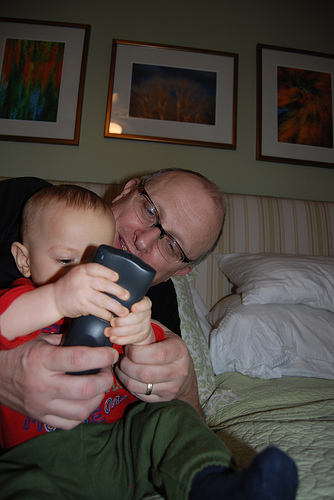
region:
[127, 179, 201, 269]
man wearing reading glasses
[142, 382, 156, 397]
man wearing a wedding ring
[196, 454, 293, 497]
baby wearing blue socks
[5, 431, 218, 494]
man wearing green pants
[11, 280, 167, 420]
baby wearing a red shirt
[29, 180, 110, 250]
baby with blonde hair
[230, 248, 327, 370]
pillows on the bed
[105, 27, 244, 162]
pictures on the wall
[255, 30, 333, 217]
pictures on the wall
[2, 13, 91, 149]
pictures on the wall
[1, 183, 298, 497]
a baby looking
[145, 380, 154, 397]
a ring on finger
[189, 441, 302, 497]
a navy blue sock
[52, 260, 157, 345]
the baby's hand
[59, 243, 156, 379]
a black remote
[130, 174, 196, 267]
glasses on face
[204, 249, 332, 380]
pillows stacked to right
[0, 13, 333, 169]
frames on the wall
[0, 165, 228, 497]
a man holding baby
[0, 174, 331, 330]
a bed frame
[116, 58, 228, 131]
A painting in the center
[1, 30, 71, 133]
A painting on the side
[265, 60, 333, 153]
A painting next to the center one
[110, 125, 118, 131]
Reflection of light on picture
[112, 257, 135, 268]
A remote control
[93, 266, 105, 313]
An infant hand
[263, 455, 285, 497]
The infant's foot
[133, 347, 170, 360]
Man's finger holding child's hand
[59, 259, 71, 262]
The child's eye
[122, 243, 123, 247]
The teeth of the man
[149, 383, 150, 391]
Ring reflecting light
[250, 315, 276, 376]
A pillow on the bed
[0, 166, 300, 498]
Man and child holding TV remote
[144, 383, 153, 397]
Ring on man's finger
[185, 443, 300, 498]
Blue sock on child's foot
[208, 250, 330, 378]
Pillows on the bed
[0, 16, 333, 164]
Framed photos on the wall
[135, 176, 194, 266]
Glasses over man's eyes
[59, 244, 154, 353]
Black television remote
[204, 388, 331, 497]
Green quilt on the bed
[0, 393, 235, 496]
Baby's green sweatpants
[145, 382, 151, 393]
the ring is gold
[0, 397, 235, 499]
the pants are green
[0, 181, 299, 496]
the child is sitting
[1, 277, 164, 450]
the shirt is red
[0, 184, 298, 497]
the child is young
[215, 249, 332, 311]
the pillow is white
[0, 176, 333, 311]
the headboard is striped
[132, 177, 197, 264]
the glasses have a black frame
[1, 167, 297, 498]
the child in front of the man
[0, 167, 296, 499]
the man behind the child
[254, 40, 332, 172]
picture of flowers with white background and brown frame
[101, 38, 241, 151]
picture of flowers with white background and brown frame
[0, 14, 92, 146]
picture of flowers with white background and brown frame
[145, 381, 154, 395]
flat gold wedding band